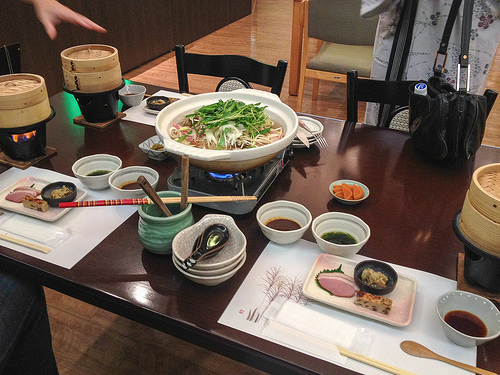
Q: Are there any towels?
A: No, there are no towels.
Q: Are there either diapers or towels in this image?
A: No, there are no towels or diapers.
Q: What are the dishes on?
A: The dishes are on the mat.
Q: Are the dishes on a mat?
A: Yes, the dishes are on a mat.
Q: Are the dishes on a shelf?
A: No, the dishes are on a mat.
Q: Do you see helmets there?
A: No, there are no helmets.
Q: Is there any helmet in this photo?
A: No, there are no helmets.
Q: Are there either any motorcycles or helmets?
A: No, there are no helmets or motorcycles.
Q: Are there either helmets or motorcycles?
A: No, there are no helmets or motorcycles.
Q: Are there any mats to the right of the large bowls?
A: Yes, there is a mat to the right of the bowls.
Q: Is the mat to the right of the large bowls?
A: Yes, the mat is to the right of the bowls.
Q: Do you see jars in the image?
A: No, there are no jars.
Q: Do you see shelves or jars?
A: No, there are no jars or shelves.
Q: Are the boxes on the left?
A: Yes, the boxes are on the left of the image.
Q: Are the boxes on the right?
A: No, the boxes are on the left of the image.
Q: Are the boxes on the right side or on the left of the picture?
A: The boxes are on the left of the image.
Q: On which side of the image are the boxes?
A: The boxes are on the left of the image.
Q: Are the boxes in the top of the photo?
A: Yes, the boxes are in the top of the image.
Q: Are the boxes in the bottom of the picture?
A: No, the boxes are in the top of the image.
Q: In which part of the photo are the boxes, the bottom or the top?
A: The boxes are in the top of the image.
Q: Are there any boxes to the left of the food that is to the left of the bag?
A: Yes, there are boxes to the left of the food.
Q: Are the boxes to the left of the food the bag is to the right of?
A: Yes, the boxes are to the left of the food.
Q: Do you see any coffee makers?
A: No, there are no coffee makers.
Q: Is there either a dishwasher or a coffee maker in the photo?
A: No, there are no coffee makers or dishwashers.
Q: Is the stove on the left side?
A: Yes, the stove is on the left of the image.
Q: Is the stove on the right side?
A: No, the stove is on the left of the image.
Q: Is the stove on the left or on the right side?
A: The stove is on the left of the image.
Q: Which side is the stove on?
A: The stove is on the left of the image.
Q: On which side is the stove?
A: The stove is on the left of the image.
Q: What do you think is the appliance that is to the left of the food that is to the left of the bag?
A: The appliance is a stove.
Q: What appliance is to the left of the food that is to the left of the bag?
A: The appliance is a stove.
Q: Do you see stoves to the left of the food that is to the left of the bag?
A: Yes, there is a stove to the left of the food.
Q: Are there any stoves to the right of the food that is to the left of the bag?
A: No, the stove is to the left of the food.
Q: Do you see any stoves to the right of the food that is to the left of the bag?
A: No, the stove is to the left of the food.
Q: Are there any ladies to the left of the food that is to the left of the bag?
A: No, there is a stove to the left of the food.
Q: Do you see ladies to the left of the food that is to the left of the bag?
A: No, there is a stove to the left of the food.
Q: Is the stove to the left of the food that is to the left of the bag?
A: Yes, the stove is to the left of the food.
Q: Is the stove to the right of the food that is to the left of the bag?
A: No, the stove is to the left of the food.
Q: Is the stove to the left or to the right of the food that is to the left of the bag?
A: The stove is to the left of the food.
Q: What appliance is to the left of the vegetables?
A: The appliance is a stove.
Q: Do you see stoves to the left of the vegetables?
A: Yes, there is a stove to the left of the vegetables.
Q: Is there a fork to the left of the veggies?
A: No, there is a stove to the left of the veggies.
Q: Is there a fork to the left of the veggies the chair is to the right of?
A: No, there is a stove to the left of the veggies.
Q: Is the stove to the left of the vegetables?
A: Yes, the stove is to the left of the vegetables.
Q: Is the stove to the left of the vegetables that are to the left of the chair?
A: Yes, the stove is to the left of the vegetables.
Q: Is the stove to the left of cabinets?
A: No, the stove is to the left of the vegetables.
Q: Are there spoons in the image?
A: Yes, there is a spoon.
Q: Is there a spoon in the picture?
A: Yes, there is a spoon.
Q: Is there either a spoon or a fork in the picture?
A: Yes, there is a spoon.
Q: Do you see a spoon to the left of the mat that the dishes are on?
A: Yes, there is a spoon to the left of the mat.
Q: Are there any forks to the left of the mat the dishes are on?
A: No, there is a spoon to the left of the mat.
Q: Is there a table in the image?
A: Yes, there is a table.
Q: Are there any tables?
A: Yes, there is a table.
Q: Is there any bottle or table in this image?
A: Yes, there is a table.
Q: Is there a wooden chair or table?
A: Yes, there is a wood table.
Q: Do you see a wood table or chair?
A: Yes, there is a wood table.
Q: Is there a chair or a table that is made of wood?
A: Yes, the table is made of wood.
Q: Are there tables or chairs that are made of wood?
A: Yes, the table is made of wood.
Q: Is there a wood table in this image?
A: Yes, there is a wood table.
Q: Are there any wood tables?
A: Yes, there is a wood table.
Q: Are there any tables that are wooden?
A: Yes, there is a table that is wooden.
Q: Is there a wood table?
A: Yes, there is a table that is made of wood.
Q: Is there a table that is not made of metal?
A: Yes, there is a table that is made of wood.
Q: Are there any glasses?
A: No, there are no glasses.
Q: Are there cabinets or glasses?
A: No, there are no glasses or cabinets.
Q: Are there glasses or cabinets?
A: No, there are no glasses or cabinets.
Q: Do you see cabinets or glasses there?
A: No, there are no glasses or cabinets.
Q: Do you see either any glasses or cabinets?
A: No, there are no glasses or cabinets.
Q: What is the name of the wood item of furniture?
A: The piece of furniture is a table.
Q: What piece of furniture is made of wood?
A: The piece of furniture is a table.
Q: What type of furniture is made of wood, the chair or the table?
A: The table is made of wood.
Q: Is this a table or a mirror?
A: This is a table.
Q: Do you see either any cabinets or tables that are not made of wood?
A: No, there is a table but it is made of wood.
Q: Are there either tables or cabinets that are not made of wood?
A: No, there is a table but it is made of wood.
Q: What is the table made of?
A: The table is made of wood.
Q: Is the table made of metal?
A: No, the table is made of wood.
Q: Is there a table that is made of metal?
A: No, there is a table but it is made of wood.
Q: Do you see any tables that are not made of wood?
A: No, there is a table but it is made of wood.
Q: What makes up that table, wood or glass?
A: The table is made of wood.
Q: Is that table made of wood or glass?
A: The table is made of wood.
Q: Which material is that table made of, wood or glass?
A: The table is made of wood.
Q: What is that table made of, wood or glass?
A: The table is made of wood.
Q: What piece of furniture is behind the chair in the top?
A: The piece of furniture is a table.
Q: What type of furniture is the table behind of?
A: The table is behind the chair.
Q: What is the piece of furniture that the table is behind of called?
A: The piece of furniture is a chair.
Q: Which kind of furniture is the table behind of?
A: The table is behind the chair.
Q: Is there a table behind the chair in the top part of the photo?
A: Yes, there is a table behind the chair.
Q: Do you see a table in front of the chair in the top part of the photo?
A: No, the table is behind the chair.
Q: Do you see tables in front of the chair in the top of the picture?
A: No, the table is behind the chair.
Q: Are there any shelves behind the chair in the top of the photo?
A: No, there is a table behind the chair.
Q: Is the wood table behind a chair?
A: Yes, the table is behind a chair.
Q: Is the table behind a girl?
A: No, the table is behind a chair.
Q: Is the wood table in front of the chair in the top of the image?
A: No, the table is behind the chair.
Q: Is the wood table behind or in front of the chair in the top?
A: The table is behind the chair.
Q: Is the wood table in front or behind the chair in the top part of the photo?
A: The table is behind the chair.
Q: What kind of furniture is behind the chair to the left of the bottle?
A: The piece of furniture is a table.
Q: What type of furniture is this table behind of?
A: The table is behind the chair.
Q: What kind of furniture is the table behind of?
A: The table is behind the chair.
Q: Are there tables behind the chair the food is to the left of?
A: Yes, there is a table behind the chair.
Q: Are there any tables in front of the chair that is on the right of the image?
A: No, the table is behind the chair.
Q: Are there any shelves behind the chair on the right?
A: No, there is a table behind the chair.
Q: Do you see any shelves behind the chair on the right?
A: No, there is a table behind the chair.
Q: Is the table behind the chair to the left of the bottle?
A: Yes, the table is behind the chair.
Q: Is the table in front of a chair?
A: No, the table is behind a chair.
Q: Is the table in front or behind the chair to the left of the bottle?
A: The table is behind the chair.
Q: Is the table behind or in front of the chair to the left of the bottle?
A: The table is behind the chair.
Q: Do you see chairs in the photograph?
A: Yes, there is a chair.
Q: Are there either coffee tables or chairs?
A: Yes, there is a chair.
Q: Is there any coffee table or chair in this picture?
A: Yes, there is a chair.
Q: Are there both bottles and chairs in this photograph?
A: Yes, there are both a chair and a bottle.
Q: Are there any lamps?
A: No, there are no lamps.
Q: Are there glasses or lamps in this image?
A: No, there are no lamps or glasses.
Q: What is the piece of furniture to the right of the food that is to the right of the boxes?
A: The piece of furniture is a chair.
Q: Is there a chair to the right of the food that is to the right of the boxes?
A: Yes, there is a chair to the right of the food.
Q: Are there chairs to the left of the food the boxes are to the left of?
A: No, the chair is to the right of the food.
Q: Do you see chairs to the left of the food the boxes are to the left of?
A: No, the chair is to the right of the food.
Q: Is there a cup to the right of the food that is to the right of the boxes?
A: No, there is a chair to the right of the food.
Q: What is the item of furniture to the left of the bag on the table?
A: The piece of furniture is a chair.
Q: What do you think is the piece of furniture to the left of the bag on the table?
A: The piece of furniture is a chair.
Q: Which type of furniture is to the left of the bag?
A: The piece of furniture is a chair.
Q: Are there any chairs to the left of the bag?
A: Yes, there is a chair to the left of the bag.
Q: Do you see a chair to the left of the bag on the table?
A: Yes, there is a chair to the left of the bag.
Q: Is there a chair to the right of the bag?
A: No, the chair is to the left of the bag.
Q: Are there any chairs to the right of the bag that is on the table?
A: No, the chair is to the left of the bag.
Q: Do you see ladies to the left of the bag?
A: No, there is a chair to the left of the bag.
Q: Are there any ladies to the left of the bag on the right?
A: No, there is a chair to the left of the bag.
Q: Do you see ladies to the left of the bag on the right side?
A: No, there is a chair to the left of the bag.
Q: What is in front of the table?
A: The chair is in front of the table.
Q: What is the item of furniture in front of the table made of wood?
A: The piece of furniture is a chair.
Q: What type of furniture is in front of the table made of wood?
A: The piece of furniture is a chair.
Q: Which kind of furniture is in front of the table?
A: The piece of furniture is a chair.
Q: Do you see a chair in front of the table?
A: Yes, there is a chair in front of the table.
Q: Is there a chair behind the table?
A: No, the chair is in front of the table.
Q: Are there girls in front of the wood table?
A: No, there is a chair in front of the table.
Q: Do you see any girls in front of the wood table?
A: No, there is a chair in front of the table.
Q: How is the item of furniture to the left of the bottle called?
A: The piece of furniture is a chair.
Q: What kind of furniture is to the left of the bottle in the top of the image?
A: The piece of furniture is a chair.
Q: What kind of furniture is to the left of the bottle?
A: The piece of furniture is a chair.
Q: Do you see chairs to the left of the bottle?
A: Yes, there is a chair to the left of the bottle.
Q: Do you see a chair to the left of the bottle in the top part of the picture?
A: Yes, there is a chair to the left of the bottle.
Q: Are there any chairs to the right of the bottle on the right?
A: No, the chair is to the left of the bottle.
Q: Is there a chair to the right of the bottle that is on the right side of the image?
A: No, the chair is to the left of the bottle.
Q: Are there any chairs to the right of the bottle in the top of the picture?
A: No, the chair is to the left of the bottle.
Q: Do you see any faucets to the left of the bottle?
A: No, there is a chair to the left of the bottle.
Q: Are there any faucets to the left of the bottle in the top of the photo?
A: No, there is a chair to the left of the bottle.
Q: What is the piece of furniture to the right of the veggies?
A: The piece of furniture is a chair.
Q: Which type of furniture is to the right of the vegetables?
A: The piece of furniture is a chair.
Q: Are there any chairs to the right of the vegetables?
A: Yes, there is a chair to the right of the vegetables.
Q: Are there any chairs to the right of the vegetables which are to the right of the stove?
A: Yes, there is a chair to the right of the vegetables.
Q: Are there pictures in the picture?
A: No, there are no pictures.